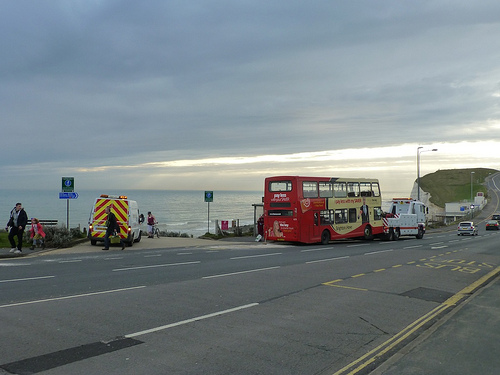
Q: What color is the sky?
A: Gray and white.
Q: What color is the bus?
A: Red and yellow.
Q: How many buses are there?
A: One.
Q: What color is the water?
A: Blue.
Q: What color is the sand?
A: Brown.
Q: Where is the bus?
A: On the road.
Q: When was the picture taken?
A: Daytime.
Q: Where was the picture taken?
A: By a lakeside area.